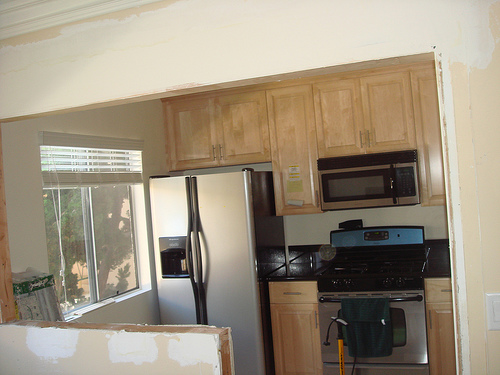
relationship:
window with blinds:
[36, 131, 152, 319] [38, 130, 148, 184]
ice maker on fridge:
[156, 234, 191, 279] [147, 170, 274, 374]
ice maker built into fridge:
[156, 234, 191, 279] [147, 170, 274, 374]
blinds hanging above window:
[38, 130, 148, 184] [36, 131, 152, 319]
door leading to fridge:
[145, 174, 197, 323] [147, 170, 274, 374]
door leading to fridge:
[190, 169, 267, 373] [147, 170, 274, 374]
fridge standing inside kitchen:
[147, 170, 274, 374] [1, 50, 466, 374]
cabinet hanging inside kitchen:
[160, 88, 219, 174] [40, 81, 496, 271]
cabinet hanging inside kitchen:
[214, 79, 273, 169] [40, 81, 496, 271]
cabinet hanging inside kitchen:
[260, 75, 324, 216] [40, 81, 496, 271]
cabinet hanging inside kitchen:
[310, 70, 367, 160] [40, 81, 496, 271]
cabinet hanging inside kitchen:
[355, 65, 416, 154] [40, 81, 496, 271]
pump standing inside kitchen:
[323, 309, 360, 374] [8, 28, 499, 373]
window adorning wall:
[41, 185, 136, 297] [3, 121, 40, 268]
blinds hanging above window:
[29, 125, 149, 189] [47, 187, 156, 305]